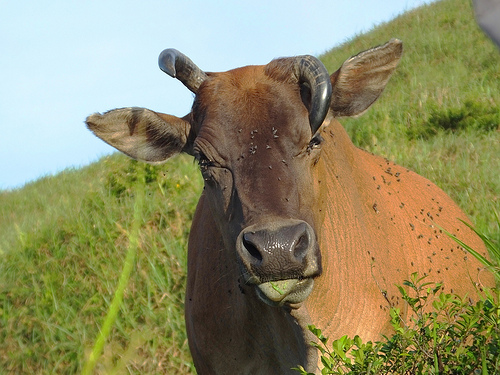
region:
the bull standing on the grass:
[83, 37, 491, 372]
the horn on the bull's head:
[155, 48, 205, 90]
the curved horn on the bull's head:
[290, 55, 330, 133]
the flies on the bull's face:
[200, 115, 313, 215]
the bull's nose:
[237, 225, 318, 281]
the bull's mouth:
[248, 271, 318, 308]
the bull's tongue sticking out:
[260, 280, 295, 300]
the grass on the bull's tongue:
[271, 280, 288, 295]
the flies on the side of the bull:
[318, 128, 496, 309]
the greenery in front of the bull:
[290, 204, 497, 374]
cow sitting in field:
[82, 40, 494, 374]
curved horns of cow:
[150, 43, 337, 141]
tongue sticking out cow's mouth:
[257, 273, 298, 301]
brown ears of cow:
[87, 35, 403, 182]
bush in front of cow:
[302, 287, 498, 374]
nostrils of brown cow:
[235, 223, 315, 259]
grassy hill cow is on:
[7, 11, 497, 358]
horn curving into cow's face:
[301, 58, 330, 130]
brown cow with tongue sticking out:
[87, 43, 497, 368]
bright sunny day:
[4, 3, 485, 347]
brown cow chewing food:
[86, 29, 493, 374]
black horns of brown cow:
[154, 40, 326, 131]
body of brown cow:
[169, 128, 478, 370]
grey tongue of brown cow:
[258, 274, 292, 300]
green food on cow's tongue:
[269, 283, 284, 298]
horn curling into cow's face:
[288, 56, 338, 131]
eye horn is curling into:
[294, 113, 334, 164]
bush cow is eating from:
[294, 279, 495, 374]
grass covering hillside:
[10, 11, 497, 365]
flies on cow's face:
[189, 123, 295, 190]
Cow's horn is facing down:
[294, 52, 335, 139]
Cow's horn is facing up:
[152, 38, 209, 91]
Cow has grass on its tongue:
[256, 277, 315, 312]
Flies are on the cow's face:
[232, 122, 300, 208]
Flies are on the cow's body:
[369, 153, 468, 275]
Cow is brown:
[85, 35, 480, 373]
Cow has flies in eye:
[187, 142, 226, 188]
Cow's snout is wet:
[233, 221, 318, 283]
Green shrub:
[308, 274, 498, 374]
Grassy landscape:
[3, 171, 185, 370]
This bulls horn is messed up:
[151, 39, 338, 149]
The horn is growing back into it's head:
[264, 41, 334, 177]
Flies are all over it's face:
[236, 115, 296, 202]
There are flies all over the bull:
[341, 127, 468, 304]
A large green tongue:
[258, 271, 313, 316]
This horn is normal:
[158, 45, 217, 97]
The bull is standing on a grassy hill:
[15, 13, 448, 323]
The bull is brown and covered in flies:
[166, 32, 451, 288]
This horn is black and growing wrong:
[284, 44, 341, 153]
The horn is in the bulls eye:
[287, 106, 340, 168]